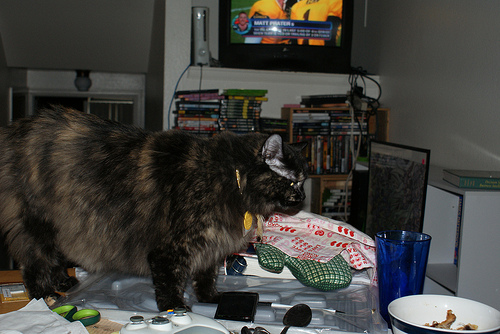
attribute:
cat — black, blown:
[0, 94, 322, 314]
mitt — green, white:
[247, 233, 364, 290]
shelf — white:
[410, 133, 499, 305]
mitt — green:
[255, 244, 358, 298]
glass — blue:
[364, 218, 415, 316]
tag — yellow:
[240, 204, 260, 237]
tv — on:
[216, 1, 353, 67]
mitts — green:
[254, 239, 357, 289]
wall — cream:
[388, 15, 485, 150]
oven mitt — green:
[249, 227, 365, 292]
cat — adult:
[14, 129, 316, 309]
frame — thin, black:
[420, 165, 436, 190]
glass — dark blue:
[372, 227, 440, 326]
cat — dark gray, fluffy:
[9, 110, 309, 331]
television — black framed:
[212, 4, 353, 74]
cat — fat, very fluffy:
[4, 100, 334, 329]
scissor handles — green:
[54, 301, 102, 328]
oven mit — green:
[252, 239, 352, 294]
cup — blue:
[377, 227, 437, 317]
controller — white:
[117, 303, 209, 331]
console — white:
[190, 6, 210, 66]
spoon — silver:
[275, 300, 320, 331]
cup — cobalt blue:
[375, 229, 435, 322]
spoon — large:
[275, 301, 303, 331]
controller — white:
[121, 307, 204, 331]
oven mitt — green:
[253, 238, 353, 291]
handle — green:
[52, 303, 105, 331]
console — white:
[194, 10, 210, 69]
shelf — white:
[436, 192, 479, 286]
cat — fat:
[8, 116, 292, 307]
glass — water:
[372, 226, 428, 295]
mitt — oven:
[286, 264, 348, 281]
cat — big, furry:
[16, 104, 304, 308]